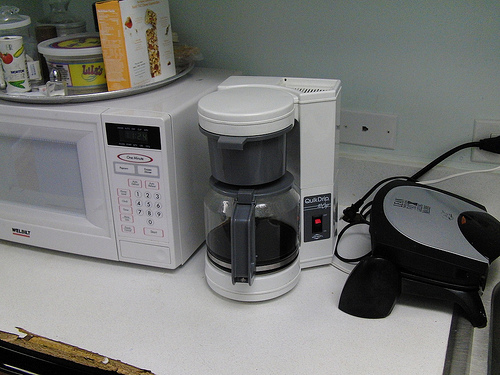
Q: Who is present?
A: Nobody.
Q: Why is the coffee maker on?
A: Making coffee.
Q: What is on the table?
A: Microwave.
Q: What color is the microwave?
A: White.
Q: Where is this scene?
A: A kitchen.